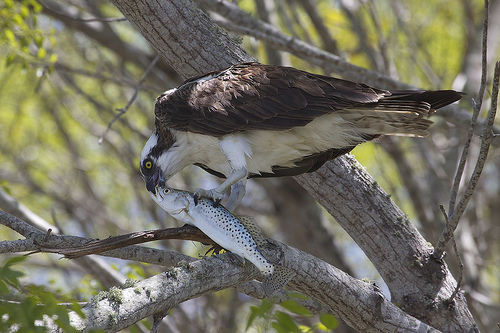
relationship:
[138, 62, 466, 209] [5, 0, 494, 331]
bird on tree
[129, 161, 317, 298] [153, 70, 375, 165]
fish eaten bird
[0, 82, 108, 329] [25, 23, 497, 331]
foliage on tree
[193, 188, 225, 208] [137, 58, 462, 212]
bird talons on bird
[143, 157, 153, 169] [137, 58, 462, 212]
eye on bird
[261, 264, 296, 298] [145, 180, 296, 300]
fish tail on fish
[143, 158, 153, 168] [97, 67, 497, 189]
eye on bird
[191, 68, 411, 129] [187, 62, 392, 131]
feathers on feathers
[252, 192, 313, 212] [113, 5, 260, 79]
wall on tree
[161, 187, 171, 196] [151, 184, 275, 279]
eye on fish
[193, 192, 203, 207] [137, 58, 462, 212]
claw on bird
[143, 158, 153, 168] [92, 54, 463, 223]
eye on bird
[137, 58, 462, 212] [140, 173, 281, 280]
bird eating fish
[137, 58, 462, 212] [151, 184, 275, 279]
bird eating fish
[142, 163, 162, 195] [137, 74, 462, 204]
beak of bird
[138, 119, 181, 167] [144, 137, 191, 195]
black stripe on head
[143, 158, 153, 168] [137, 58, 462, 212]
eye of bird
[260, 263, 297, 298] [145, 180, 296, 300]
fish tail of fish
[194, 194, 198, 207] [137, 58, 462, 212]
claw of bird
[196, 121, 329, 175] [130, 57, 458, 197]
underbelly of bird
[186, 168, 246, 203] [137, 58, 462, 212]
leg of bird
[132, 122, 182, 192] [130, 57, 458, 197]
head on bird